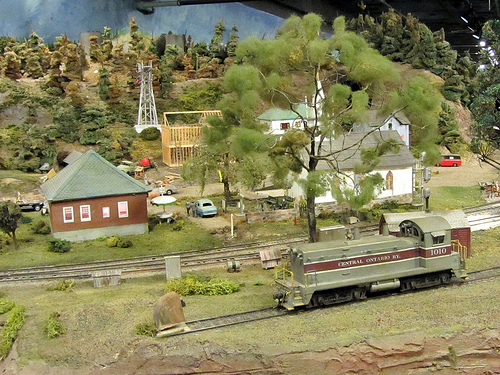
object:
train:
[272, 209, 472, 312]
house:
[39, 150, 152, 243]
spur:
[155, 266, 500, 337]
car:
[195, 198, 218, 218]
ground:
[0, 53, 499, 374]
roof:
[39, 149, 154, 202]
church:
[284, 130, 418, 218]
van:
[431, 153, 462, 167]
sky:
[0, 0, 500, 62]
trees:
[0, 1, 500, 244]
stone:
[1, 177, 24, 184]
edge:
[4, 174, 14, 187]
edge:
[315, 267, 452, 291]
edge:
[49, 189, 152, 203]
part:
[275, 264, 293, 286]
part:
[89, 293, 118, 320]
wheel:
[35, 206, 41, 211]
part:
[33, 206, 46, 214]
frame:
[161, 110, 240, 167]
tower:
[134, 57, 162, 133]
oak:
[179, 11, 441, 243]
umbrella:
[150, 196, 176, 213]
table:
[156, 211, 176, 225]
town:
[0, 73, 499, 374]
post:
[228, 211, 236, 243]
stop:
[152, 292, 186, 329]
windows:
[62, 206, 75, 223]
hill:
[0, 31, 475, 167]